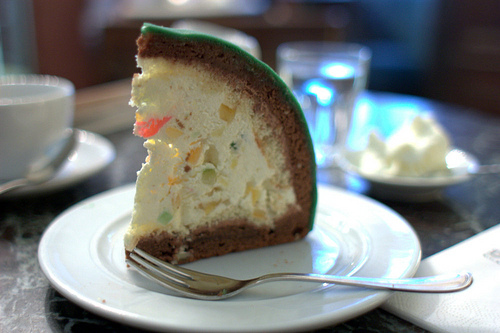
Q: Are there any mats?
A: No, there are no mats.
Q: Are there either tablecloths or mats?
A: No, there are no mats or tablecloths.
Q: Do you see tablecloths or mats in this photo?
A: No, there are no mats or tablecloths.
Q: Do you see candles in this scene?
A: No, there are no candles.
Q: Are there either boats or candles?
A: No, there are no candles or boats.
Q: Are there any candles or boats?
A: No, there are no candles or boats.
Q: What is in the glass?
A: The water is in the glass.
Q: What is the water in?
A: The water is in the glass.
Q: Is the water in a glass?
A: Yes, the water is in a glass.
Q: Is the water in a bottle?
A: No, the water is in a glass.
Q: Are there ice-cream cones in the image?
A: No, there are no ice-cream cones.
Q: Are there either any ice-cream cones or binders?
A: No, there are no ice-cream cones or binders.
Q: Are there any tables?
A: Yes, there is a table.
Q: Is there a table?
A: Yes, there is a table.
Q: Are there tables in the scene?
A: Yes, there is a table.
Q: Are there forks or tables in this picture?
A: Yes, there is a table.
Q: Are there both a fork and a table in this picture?
A: Yes, there are both a table and a fork.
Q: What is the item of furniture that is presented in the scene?
A: The piece of furniture is a table.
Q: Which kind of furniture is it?
A: The piece of furniture is a table.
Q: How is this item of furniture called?
A: This is a table.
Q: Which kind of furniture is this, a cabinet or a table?
A: This is a table.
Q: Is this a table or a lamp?
A: This is a table.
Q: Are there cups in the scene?
A: Yes, there is a cup.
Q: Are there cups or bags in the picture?
A: Yes, there is a cup.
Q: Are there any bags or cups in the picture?
A: Yes, there is a cup.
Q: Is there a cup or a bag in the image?
A: Yes, there is a cup.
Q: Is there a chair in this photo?
A: No, there are no chairs.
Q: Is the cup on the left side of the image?
A: Yes, the cup is on the left of the image.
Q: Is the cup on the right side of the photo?
A: No, the cup is on the left of the image.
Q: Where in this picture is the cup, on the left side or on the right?
A: The cup is on the left of the image.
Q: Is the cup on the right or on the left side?
A: The cup is on the left of the image.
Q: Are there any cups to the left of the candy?
A: Yes, there is a cup to the left of the candy.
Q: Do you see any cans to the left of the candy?
A: No, there is a cup to the left of the candy.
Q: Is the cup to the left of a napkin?
A: No, the cup is to the left of a candy.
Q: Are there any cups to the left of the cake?
A: Yes, there is a cup to the left of the cake.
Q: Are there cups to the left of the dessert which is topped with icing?
A: Yes, there is a cup to the left of the cake.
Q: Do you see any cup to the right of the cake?
A: No, the cup is to the left of the cake.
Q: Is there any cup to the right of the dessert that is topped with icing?
A: No, the cup is to the left of the cake.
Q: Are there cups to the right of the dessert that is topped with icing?
A: No, the cup is to the left of the cake.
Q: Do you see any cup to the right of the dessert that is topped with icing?
A: No, the cup is to the left of the cake.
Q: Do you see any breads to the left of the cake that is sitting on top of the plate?
A: No, there is a cup to the left of the cake.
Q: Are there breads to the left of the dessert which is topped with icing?
A: No, there is a cup to the left of the cake.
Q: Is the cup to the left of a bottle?
A: No, the cup is to the left of the cake.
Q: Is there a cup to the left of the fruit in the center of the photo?
A: Yes, there is a cup to the left of the fruit.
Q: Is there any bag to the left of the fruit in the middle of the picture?
A: No, there is a cup to the left of the fruit.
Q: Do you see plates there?
A: Yes, there is a plate.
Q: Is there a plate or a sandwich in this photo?
A: Yes, there is a plate.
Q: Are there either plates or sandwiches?
A: Yes, there is a plate.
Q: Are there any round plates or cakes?
A: Yes, there is a round plate.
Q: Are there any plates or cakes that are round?
A: Yes, the plate is round.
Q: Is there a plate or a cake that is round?
A: Yes, the plate is round.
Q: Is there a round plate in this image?
A: Yes, there is a round plate.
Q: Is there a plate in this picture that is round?
A: Yes, there is a plate that is round.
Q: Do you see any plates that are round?
A: Yes, there is a plate that is round.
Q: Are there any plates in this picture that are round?
A: Yes, there is a plate that is round.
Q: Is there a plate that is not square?
A: Yes, there is a round plate.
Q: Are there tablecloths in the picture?
A: No, there are no tablecloths.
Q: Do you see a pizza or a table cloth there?
A: No, there are no tablecloths or pizzas.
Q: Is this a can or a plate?
A: This is a plate.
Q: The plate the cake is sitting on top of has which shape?
A: The plate is round.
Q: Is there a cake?
A: Yes, there is a cake.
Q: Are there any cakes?
A: Yes, there is a cake.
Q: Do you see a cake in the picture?
A: Yes, there is a cake.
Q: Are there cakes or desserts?
A: Yes, there is a cake.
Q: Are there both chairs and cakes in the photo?
A: No, there is a cake but no chairs.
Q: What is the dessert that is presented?
A: The dessert is a cake.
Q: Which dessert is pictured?
A: The dessert is a cake.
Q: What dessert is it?
A: The dessert is a cake.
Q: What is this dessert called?
A: This is a cake.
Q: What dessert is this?
A: This is a cake.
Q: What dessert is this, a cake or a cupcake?
A: This is a cake.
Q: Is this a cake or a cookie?
A: This is a cake.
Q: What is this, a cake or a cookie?
A: This is a cake.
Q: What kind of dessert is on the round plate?
A: The dessert is a cake.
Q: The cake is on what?
A: The cake is on the plate.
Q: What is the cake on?
A: The cake is on the plate.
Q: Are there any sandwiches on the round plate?
A: No, there is a cake on the plate.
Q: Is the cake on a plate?
A: Yes, the cake is on a plate.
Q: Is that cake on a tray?
A: No, the cake is on a plate.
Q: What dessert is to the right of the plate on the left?
A: The dessert is a cake.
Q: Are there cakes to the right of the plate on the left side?
A: Yes, there is a cake to the right of the plate.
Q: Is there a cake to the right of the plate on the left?
A: Yes, there is a cake to the right of the plate.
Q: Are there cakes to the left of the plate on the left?
A: No, the cake is to the right of the plate.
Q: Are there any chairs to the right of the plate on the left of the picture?
A: No, there is a cake to the right of the plate.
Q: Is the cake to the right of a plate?
A: Yes, the cake is to the right of a plate.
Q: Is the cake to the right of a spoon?
A: No, the cake is to the right of a plate.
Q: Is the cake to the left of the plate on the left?
A: No, the cake is to the right of the plate.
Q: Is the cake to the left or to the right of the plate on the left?
A: The cake is to the right of the plate.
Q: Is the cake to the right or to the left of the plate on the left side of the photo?
A: The cake is to the right of the plate.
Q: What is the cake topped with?
A: The cake is topped with icing.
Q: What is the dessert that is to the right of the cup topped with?
A: The cake is topped with icing.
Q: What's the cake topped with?
A: The cake is topped with icing.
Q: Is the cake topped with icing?
A: Yes, the cake is topped with icing.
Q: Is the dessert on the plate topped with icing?
A: Yes, the cake is topped with icing.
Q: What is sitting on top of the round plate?
A: The cake is sitting on top of the plate.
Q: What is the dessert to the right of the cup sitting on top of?
A: The cake is sitting on top of the plate.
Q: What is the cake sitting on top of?
A: The cake is sitting on top of the plate.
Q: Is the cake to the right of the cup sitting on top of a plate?
A: Yes, the cake is sitting on top of a plate.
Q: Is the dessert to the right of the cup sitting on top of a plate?
A: Yes, the cake is sitting on top of a plate.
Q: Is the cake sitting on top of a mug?
A: No, the cake is sitting on top of a plate.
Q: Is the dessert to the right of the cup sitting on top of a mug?
A: No, the cake is sitting on top of a plate.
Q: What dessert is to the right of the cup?
A: The dessert is a cake.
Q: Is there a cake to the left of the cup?
A: No, the cake is to the right of the cup.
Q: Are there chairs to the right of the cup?
A: No, there is a cake to the right of the cup.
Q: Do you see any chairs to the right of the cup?
A: No, there is a cake to the right of the cup.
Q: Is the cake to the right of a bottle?
A: No, the cake is to the right of the cup.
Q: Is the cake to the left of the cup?
A: No, the cake is to the right of the cup.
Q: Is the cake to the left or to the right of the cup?
A: The cake is to the right of the cup.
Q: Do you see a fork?
A: Yes, there is a fork.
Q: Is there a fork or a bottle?
A: Yes, there is a fork.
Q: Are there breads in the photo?
A: No, there are no breads.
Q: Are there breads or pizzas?
A: No, there are no breads or pizzas.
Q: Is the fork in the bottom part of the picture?
A: Yes, the fork is in the bottom of the image.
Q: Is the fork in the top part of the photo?
A: No, the fork is in the bottom of the image.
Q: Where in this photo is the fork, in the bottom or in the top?
A: The fork is in the bottom of the image.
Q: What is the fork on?
A: The fork is on the plate.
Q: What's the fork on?
A: The fork is on the plate.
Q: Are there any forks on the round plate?
A: Yes, there is a fork on the plate.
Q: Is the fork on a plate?
A: Yes, the fork is on a plate.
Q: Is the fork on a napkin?
A: No, the fork is on a plate.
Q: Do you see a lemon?
A: No, there are no lemons.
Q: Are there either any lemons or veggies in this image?
A: No, there are no lemons or veggies.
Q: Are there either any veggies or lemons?
A: No, there are no lemons or veggies.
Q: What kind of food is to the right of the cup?
A: The food is a candy.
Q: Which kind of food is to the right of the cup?
A: The food is a candy.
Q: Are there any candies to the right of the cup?
A: Yes, there is a candy to the right of the cup.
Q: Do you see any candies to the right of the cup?
A: Yes, there is a candy to the right of the cup.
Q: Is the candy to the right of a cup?
A: Yes, the candy is to the right of a cup.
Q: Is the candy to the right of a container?
A: No, the candy is to the right of a cup.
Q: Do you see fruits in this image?
A: Yes, there is a fruit.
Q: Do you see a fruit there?
A: Yes, there is a fruit.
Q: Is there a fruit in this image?
A: Yes, there is a fruit.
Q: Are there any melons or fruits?
A: Yes, there is a fruit.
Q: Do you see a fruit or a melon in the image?
A: Yes, there is a fruit.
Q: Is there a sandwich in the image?
A: No, there are no sandwiches.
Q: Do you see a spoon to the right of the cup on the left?
A: No, there is a fruit to the right of the cup.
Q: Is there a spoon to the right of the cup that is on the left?
A: No, there is a fruit to the right of the cup.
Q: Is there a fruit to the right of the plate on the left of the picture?
A: Yes, there is a fruit to the right of the plate.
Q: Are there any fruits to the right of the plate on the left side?
A: Yes, there is a fruit to the right of the plate.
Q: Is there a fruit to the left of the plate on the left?
A: No, the fruit is to the right of the plate.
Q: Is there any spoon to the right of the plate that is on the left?
A: No, there is a fruit to the right of the plate.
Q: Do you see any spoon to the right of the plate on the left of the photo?
A: No, there is a fruit to the right of the plate.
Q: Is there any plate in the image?
A: Yes, there is a plate.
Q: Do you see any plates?
A: Yes, there is a plate.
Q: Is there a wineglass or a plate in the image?
A: Yes, there is a plate.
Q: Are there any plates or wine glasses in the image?
A: Yes, there is a plate.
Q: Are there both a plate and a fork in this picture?
A: Yes, there are both a plate and a fork.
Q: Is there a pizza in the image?
A: No, there are no pizzas.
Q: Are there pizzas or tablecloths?
A: No, there are no pizzas or tablecloths.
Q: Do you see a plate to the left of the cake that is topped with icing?
A: Yes, there is a plate to the left of the cake.